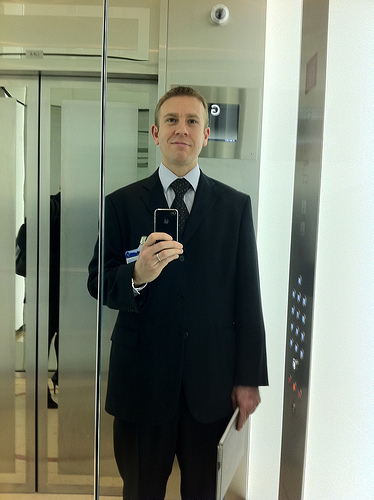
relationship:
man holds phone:
[90, 78, 271, 497] [151, 207, 185, 255]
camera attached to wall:
[209, 3, 229, 25] [158, 1, 265, 239]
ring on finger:
[155, 252, 161, 264] [146, 249, 187, 259]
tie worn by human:
[169, 178, 193, 230] [85, 84, 268, 496]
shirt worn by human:
[155, 165, 176, 204] [109, 53, 258, 369]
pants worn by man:
[103, 418, 221, 498] [83, 78, 271, 497]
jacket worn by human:
[89, 163, 265, 419] [85, 84, 268, 496]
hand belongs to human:
[131, 231, 181, 285] [85, 84, 268, 496]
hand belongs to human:
[128, 224, 182, 285] [85, 84, 268, 496]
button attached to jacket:
[178, 328, 197, 344] [89, 163, 265, 419]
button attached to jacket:
[173, 252, 190, 271] [88, 168, 258, 320]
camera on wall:
[209, 3, 229, 25] [153, 1, 266, 498]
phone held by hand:
[151, 204, 180, 242] [131, 231, 181, 285]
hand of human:
[131, 231, 181, 285] [97, 87, 275, 454]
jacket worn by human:
[86, 163, 268, 423] [85, 84, 268, 496]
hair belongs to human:
[152, 82, 211, 126] [85, 84, 268, 496]